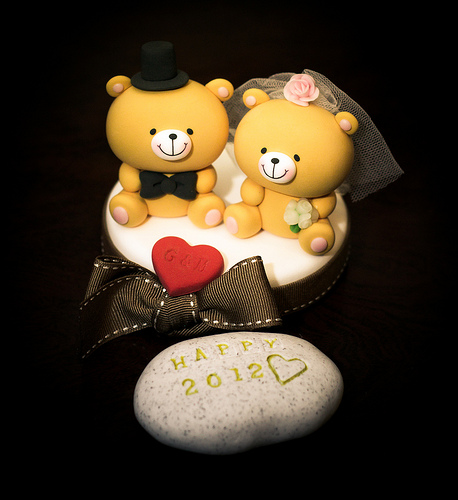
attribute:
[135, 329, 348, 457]
stone — smooth, memorabilia, white, grey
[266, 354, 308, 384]
heart — green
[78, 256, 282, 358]
ribbon — black, dark brown, brown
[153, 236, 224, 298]
heart — clay, red, small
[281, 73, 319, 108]
rose — pink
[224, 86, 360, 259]
bear — wedded, yellow, bride, groom, orange, smiling, tiny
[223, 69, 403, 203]
veil — white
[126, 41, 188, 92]
top hat — tiny, black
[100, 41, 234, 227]
bear — wedded, yellow, groom, orange, smilling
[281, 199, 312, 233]
flower — green, white, tiny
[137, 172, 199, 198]
bow tie — black, small